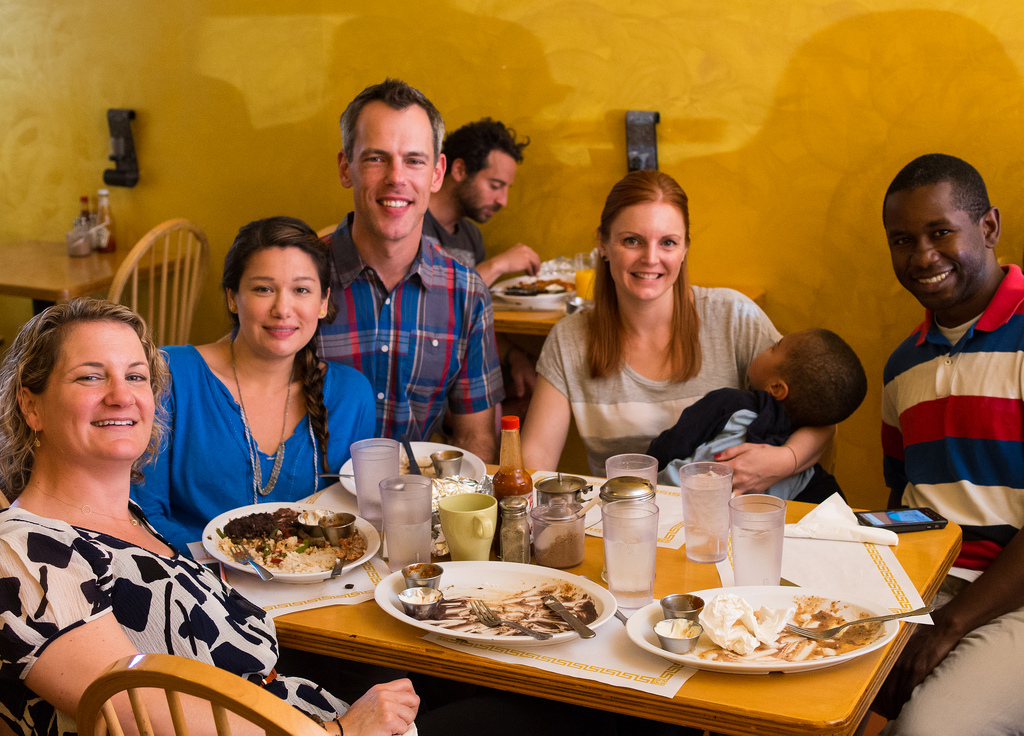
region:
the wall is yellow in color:
[697, 75, 852, 228]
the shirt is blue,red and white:
[898, 338, 1012, 494]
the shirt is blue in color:
[176, 388, 234, 488]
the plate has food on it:
[220, 505, 354, 576]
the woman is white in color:
[594, 158, 709, 370]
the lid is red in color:
[495, 411, 530, 440]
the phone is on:
[863, 509, 943, 532]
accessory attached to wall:
[104, 105, 147, 186]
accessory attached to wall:
[614, 112, 665, 164]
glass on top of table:
[728, 493, 782, 580]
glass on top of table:
[610, 493, 653, 599]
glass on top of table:
[686, 466, 721, 556]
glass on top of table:
[380, 474, 442, 564]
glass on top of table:
[348, 437, 403, 507]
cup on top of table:
[440, 487, 494, 563]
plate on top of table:
[623, 570, 899, 672]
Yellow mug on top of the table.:
[439, 481, 501, 562]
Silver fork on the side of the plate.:
[777, 601, 952, 656]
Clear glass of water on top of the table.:
[670, 451, 722, 579]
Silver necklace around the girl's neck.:
[221, 332, 285, 503]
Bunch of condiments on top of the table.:
[65, 152, 129, 261]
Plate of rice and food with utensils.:
[205, 499, 379, 598]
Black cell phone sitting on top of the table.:
[849, 499, 954, 538]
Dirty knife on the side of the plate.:
[527, 574, 595, 645]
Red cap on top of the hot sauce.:
[491, 410, 521, 429]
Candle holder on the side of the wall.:
[104, 95, 144, 193]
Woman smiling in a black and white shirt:
[7, 296, 186, 733]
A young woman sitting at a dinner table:
[143, 217, 372, 512]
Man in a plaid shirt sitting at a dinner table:
[310, 66, 497, 471]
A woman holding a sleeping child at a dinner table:
[495, 170, 868, 488]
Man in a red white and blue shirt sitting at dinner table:
[851, 149, 1022, 718]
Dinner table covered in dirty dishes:
[191, 421, 961, 726]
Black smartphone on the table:
[854, 506, 947, 536]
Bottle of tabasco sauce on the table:
[487, 410, 541, 560]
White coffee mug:
[431, 489, 499, 563]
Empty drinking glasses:
[330, 435, 445, 571]